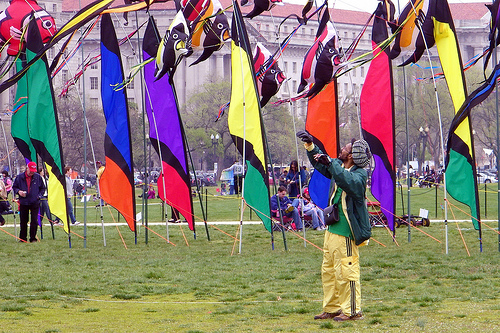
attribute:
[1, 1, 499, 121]
building — large, public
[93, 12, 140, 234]
flag — blue, red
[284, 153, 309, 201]
man — visible.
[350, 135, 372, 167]
headdress — round striped 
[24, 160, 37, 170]
cap — red, ball cap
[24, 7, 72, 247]
flag — green, yellow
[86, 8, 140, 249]
flag — blue , black , orange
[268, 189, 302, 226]
man — sitting.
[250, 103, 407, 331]
man — visible.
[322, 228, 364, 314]
pants — yellow, flight pants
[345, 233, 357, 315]
stripes — black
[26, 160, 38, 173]
baseball cap — red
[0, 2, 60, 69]
clownfish — wind flyer, red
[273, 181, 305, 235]
man — white 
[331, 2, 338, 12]
roof — red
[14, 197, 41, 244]
jeans — black old man 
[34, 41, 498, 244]
flag — red, purple, black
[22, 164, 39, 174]
cap — red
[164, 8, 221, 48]
kite — fish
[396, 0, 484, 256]
flag — black , yellow green 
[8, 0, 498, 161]
building — background.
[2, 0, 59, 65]
fish — red, white, black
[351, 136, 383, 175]
hat — crocheted, dreads hat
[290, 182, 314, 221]
woman — sitting.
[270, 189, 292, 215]
coat — blue 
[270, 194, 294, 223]
person — together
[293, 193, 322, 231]
person — together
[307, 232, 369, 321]
pants — yellow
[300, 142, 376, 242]
shirt — green